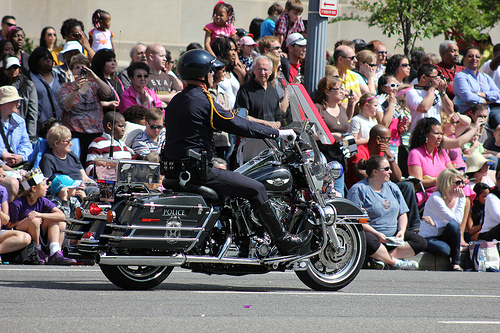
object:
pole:
[301, 0, 326, 101]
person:
[345, 155, 428, 271]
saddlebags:
[63, 183, 212, 251]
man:
[158, 48, 314, 257]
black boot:
[252, 199, 313, 256]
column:
[303, 0, 328, 102]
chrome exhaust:
[95, 252, 187, 266]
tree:
[328, 0, 500, 59]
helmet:
[176, 49, 225, 91]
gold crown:
[13, 166, 49, 201]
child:
[9, 165, 77, 265]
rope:
[200, 84, 235, 129]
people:
[375, 74, 413, 179]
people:
[384, 54, 411, 85]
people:
[364, 39, 388, 82]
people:
[352, 50, 381, 96]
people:
[333, 45, 362, 123]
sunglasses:
[400, 63, 408, 67]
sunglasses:
[378, 50, 388, 54]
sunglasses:
[366, 62, 377, 66]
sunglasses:
[346, 56, 356, 61]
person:
[407, 117, 477, 247]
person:
[405, 63, 455, 150]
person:
[452, 48, 500, 125]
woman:
[118, 62, 165, 118]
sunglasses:
[137, 75, 150, 78]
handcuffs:
[178, 170, 191, 186]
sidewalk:
[0, 32, 500, 271]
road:
[1, 264, 498, 333]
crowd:
[0, 0, 500, 272]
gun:
[187, 149, 209, 181]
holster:
[194, 154, 209, 180]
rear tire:
[98, 244, 180, 291]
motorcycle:
[62, 81, 373, 292]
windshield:
[280, 81, 308, 130]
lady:
[418, 168, 464, 271]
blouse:
[418, 191, 467, 238]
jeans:
[427, 220, 462, 265]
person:
[42, 124, 100, 195]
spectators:
[0, 0, 500, 273]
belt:
[159, 156, 212, 175]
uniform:
[158, 84, 279, 207]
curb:
[412, 251, 451, 271]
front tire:
[293, 224, 367, 291]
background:
[284, 9, 483, 79]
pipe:
[95, 252, 260, 267]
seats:
[297, 73, 433, 169]